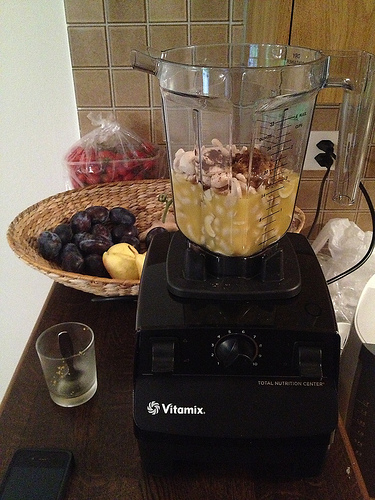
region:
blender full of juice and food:
[131, 39, 366, 475]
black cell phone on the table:
[0, 445, 76, 499]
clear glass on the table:
[35, 321, 96, 406]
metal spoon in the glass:
[55, 332, 81, 382]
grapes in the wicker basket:
[37, 206, 165, 274]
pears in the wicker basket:
[102, 242, 146, 279]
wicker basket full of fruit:
[8, 179, 304, 297]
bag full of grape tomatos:
[65, 114, 159, 184]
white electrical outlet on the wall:
[304, 130, 337, 174]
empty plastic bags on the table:
[313, 221, 374, 314]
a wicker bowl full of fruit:
[7, 176, 305, 298]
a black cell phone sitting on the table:
[2, 443, 72, 497]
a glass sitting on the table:
[33, 321, 99, 408]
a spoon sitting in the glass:
[55, 328, 84, 384]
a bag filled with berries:
[63, 134, 153, 188]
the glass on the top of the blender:
[129, 41, 374, 251]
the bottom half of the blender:
[128, 227, 345, 477]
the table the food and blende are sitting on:
[5, 285, 371, 497]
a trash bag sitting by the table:
[312, 215, 374, 321]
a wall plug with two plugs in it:
[306, 130, 343, 176]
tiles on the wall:
[68, 0, 236, 123]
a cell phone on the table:
[2, 446, 81, 496]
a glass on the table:
[34, 322, 97, 407]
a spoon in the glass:
[57, 330, 81, 376]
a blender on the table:
[146, 81, 334, 448]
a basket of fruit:
[33, 170, 161, 285]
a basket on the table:
[5, 175, 305, 286]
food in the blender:
[174, 150, 301, 251]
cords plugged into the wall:
[313, 138, 333, 168]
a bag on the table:
[325, 210, 372, 288]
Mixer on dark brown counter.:
[131, 45, 374, 442]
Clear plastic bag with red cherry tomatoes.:
[52, 119, 166, 185]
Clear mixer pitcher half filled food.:
[128, 40, 368, 253]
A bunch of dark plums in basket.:
[42, 205, 171, 269]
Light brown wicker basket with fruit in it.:
[5, 176, 311, 297]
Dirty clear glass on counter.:
[31, 321, 108, 409]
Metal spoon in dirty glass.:
[56, 327, 88, 389]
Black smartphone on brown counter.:
[0, 447, 75, 498]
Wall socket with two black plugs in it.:
[304, 130, 336, 175]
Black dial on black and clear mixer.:
[212, 332, 258, 375]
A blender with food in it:
[126, 38, 371, 484]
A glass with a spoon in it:
[33, 318, 100, 411]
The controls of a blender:
[145, 325, 329, 391]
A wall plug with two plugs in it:
[303, 128, 355, 178]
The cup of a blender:
[126, 39, 372, 260]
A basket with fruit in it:
[5, 174, 308, 300]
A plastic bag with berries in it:
[60, 107, 166, 187]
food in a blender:
[168, 136, 303, 259]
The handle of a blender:
[325, 50, 372, 209]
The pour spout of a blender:
[125, 38, 164, 76]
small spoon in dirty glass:
[35, 320, 98, 408]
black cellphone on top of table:
[0, 446, 75, 498]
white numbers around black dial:
[209, 326, 263, 369]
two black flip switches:
[148, 339, 325, 382]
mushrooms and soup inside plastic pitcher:
[131, 39, 329, 257]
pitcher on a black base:
[126, 39, 341, 478]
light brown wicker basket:
[7, 176, 305, 296]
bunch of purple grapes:
[37, 202, 167, 277]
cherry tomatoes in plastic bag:
[56, 108, 164, 187]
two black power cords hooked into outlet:
[298, 127, 373, 283]